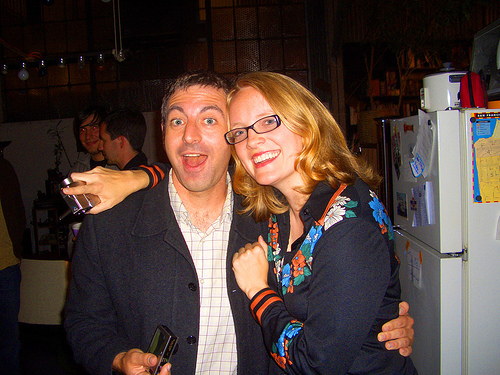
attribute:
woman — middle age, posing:
[226, 79, 411, 370]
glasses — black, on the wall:
[222, 115, 284, 147]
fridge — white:
[381, 105, 499, 374]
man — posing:
[68, 74, 281, 375]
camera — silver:
[145, 326, 178, 370]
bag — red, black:
[455, 70, 483, 107]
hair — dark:
[157, 66, 236, 110]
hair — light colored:
[225, 67, 371, 194]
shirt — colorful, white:
[171, 181, 252, 374]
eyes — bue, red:
[165, 112, 223, 131]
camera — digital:
[60, 168, 105, 215]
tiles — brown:
[3, 2, 312, 101]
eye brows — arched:
[161, 101, 229, 124]